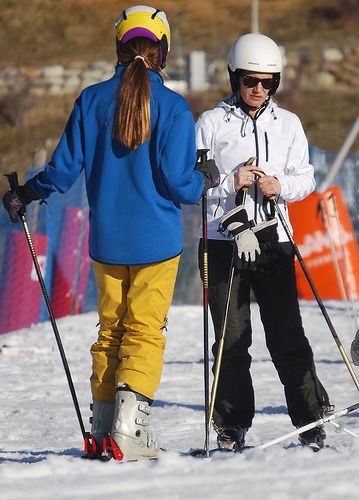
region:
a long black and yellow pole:
[257, 194, 357, 392]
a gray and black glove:
[218, 207, 266, 274]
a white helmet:
[223, 29, 288, 99]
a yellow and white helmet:
[113, 2, 175, 72]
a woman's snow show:
[105, 379, 162, 464]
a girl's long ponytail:
[115, 50, 155, 150]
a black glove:
[1, 187, 29, 223]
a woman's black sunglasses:
[233, 70, 278, 93]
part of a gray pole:
[247, 2, 264, 36]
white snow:
[0, 297, 358, 495]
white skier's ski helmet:
[225, 29, 283, 97]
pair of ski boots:
[82, 379, 177, 466]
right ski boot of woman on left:
[104, 380, 169, 463]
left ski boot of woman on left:
[82, 393, 116, 460]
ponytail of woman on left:
[111, 34, 168, 150]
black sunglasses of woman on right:
[236, 67, 279, 92]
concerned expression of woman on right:
[225, 30, 284, 114]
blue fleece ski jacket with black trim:
[14, 56, 230, 273]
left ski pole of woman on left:
[2, 166, 99, 460]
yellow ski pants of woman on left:
[82, 247, 180, 407]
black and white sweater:
[193, 99, 316, 238]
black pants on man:
[199, 214, 327, 444]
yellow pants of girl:
[84, 216, 184, 408]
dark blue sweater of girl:
[22, 58, 204, 267]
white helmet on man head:
[223, 27, 282, 103]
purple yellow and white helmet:
[110, 3, 175, 62]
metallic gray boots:
[79, 386, 166, 458]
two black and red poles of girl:
[6, 146, 213, 456]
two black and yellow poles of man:
[204, 163, 356, 454]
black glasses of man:
[234, 70, 275, 89]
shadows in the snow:
[2, 414, 75, 469]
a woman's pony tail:
[114, 48, 148, 147]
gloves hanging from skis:
[223, 180, 289, 272]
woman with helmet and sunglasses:
[219, 25, 279, 100]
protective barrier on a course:
[0, 221, 90, 328]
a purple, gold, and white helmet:
[108, 0, 167, 43]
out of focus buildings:
[3, 52, 66, 98]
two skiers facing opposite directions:
[72, 2, 302, 165]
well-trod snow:
[3, 359, 56, 429]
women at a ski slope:
[18, 5, 333, 392]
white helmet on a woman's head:
[225, 31, 283, 108]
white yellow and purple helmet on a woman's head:
[114, 4, 172, 67]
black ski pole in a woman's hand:
[200, 148, 210, 458]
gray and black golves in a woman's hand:
[215, 203, 268, 271]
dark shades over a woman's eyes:
[240, 73, 276, 90]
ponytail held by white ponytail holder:
[114, 50, 153, 152]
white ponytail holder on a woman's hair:
[133, 54, 146, 59]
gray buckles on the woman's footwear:
[133, 403, 151, 425]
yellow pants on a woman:
[91, 253, 183, 400]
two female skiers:
[2, 0, 355, 465]